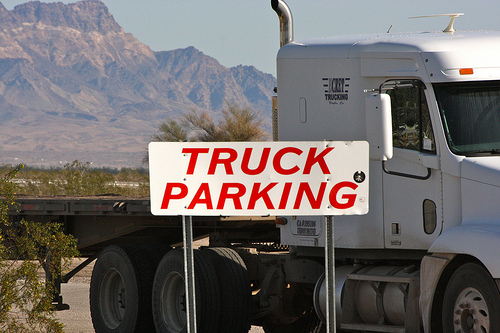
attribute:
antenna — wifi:
[402, 7, 474, 35]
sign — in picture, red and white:
[148, 140, 368, 217]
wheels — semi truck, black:
[95, 231, 292, 331]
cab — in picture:
[254, 12, 496, 322]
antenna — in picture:
[406, 11, 468, 35]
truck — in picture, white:
[0, 0, 498, 330]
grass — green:
[56, 150, 136, 192]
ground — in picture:
[412, 180, 457, 228]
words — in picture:
[164, 131, 376, 221]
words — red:
[144, 134, 374, 224]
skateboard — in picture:
[388, 78, 427, 162]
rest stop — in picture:
[0, 94, 421, 327]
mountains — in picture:
[48, 19, 140, 116]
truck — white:
[50, 44, 497, 321]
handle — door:
[389, 220, 401, 238]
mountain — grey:
[4, 0, 256, 115]